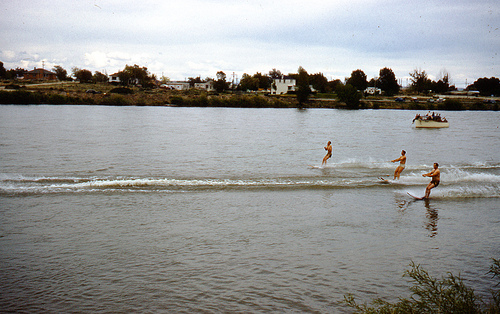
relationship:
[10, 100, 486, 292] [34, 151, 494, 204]
water has waves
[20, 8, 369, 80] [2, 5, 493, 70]
clouds in sky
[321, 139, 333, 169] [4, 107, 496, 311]
man skiing on river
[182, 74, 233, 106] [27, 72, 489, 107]
house on river bank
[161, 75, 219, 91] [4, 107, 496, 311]
house near river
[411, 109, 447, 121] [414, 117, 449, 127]
people in boat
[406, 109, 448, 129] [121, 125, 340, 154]
boat in water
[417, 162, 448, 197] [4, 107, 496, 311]
man on river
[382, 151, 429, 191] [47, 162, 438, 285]
man on river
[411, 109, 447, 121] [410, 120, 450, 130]
people are inside boat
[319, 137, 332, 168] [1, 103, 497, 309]
woman doing tricks in water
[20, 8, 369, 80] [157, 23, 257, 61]
clouds in sky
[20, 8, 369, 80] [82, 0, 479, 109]
clouds in sky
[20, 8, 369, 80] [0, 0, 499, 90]
clouds in sky